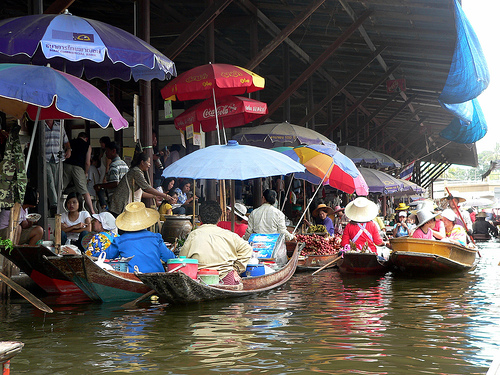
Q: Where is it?
A: This is at the pond.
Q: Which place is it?
A: It is a pond.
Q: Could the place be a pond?
A: Yes, it is a pond.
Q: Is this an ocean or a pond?
A: It is a pond.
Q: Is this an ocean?
A: No, it is a pond.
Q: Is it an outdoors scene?
A: Yes, it is outdoors.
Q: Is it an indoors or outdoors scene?
A: It is outdoors.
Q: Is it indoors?
A: No, it is outdoors.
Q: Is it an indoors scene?
A: No, it is outdoors.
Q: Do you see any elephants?
A: No, there are no elephants.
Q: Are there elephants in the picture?
A: No, there are no elephants.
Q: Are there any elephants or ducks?
A: No, there are no elephants or ducks.